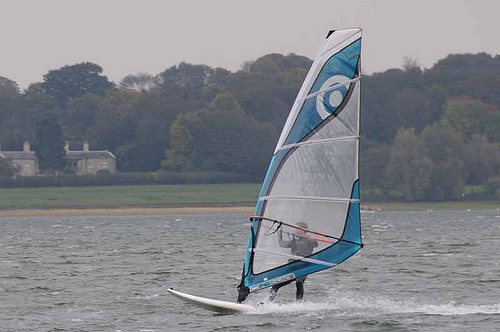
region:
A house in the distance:
[0, 137, 125, 186]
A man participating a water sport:
[152, 27, 382, 315]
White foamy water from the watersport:
[262, 290, 499, 320]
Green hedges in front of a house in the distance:
[5, 171, 187, 183]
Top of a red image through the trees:
[436, 88, 498, 115]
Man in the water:
[263, 220, 317, 302]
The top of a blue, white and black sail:
[266, 25, 367, 144]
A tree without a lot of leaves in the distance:
[116, 65, 168, 97]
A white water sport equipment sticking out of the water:
[161, 284, 249, 318]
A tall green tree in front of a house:
[26, 91, 70, 182]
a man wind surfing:
[22, 37, 472, 320]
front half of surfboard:
[151, 283, 381, 322]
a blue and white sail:
[239, 22, 394, 304]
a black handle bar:
[231, 199, 381, 251]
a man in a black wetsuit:
[260, 209, 326, 320]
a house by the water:
[0, 107, 175, 240]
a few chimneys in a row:
[17, 133, 99, 158]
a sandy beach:
[36, 191, 243, 243]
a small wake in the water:
[306, 287, 471, 324]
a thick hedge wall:
[48, 164, 264, 196]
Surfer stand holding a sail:
[153, 18, 404, 328]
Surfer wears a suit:
[265, 217, 320, 302]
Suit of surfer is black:
[265, 215, 325, 310]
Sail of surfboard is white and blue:
[230, 17, 385, 302]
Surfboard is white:
[160, 280, 260, 330]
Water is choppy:
[269, 288, 496, 330]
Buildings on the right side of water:
[8, 131, 120, 186]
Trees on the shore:
[14, 48, 479, 185]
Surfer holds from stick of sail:
[240, 208, 365, 257]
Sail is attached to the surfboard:
[211, 274, 259, 316]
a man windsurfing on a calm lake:
[173, 61, 350, 320]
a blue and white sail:
[262, 46, 393, 194]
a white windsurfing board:
[154, 268, 334, 324]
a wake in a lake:
[309, 292, 494, 328]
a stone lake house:
[5, 118, 154, 288]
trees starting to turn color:
[388, 93, 488, 243]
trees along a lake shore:
[382, 98, 493, 255]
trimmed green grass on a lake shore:
[27, 177, 247, 234]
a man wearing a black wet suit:
[260, 211, 340, 306]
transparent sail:
[277, 137, 362, 234]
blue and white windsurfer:
[175, 17, 381, 314]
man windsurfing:
[167, 24, 394, 326]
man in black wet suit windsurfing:
[165, 11, 390, 322]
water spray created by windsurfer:
[254, 290, 483, 322]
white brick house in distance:
[13, 124, 131, 192]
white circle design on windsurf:
[308, 66, 365, 128]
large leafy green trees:
[122, 63, 262, 176]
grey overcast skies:
[86, 13, 264, 45]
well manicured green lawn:
[57, 185, 227, 208]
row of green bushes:
[14, 164, 231, 187]